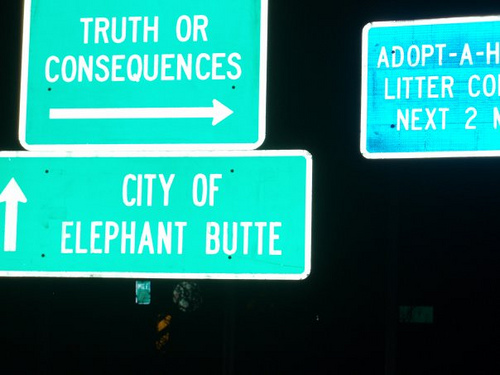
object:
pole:
[157, 315, 173, 333]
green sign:
[0, 155, 307, 275]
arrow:
[0, 177, 29, 252]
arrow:
[48, 98, 236, 128]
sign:
[16, 0, 267, 151]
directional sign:
[0, 149, 316, 282]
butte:
[205, 221, 283, 256]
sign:
[357, 14, 500, 160]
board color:
[364, 20, 500, 152]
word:
[44, 51, 244, 83]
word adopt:
[375, 43, 448, 69]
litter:
[383, 75, 456, 100]